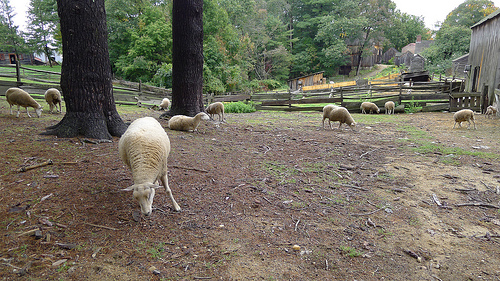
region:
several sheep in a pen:
[5, 80, 497, 241]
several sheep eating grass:
[6, 75, 493, 218]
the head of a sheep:
[116, 176, 161, 221]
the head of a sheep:
[345, 118, 360, 130]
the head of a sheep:
[193, 109, 210, 124]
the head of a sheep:
[33, 100, 43, 119]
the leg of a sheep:
[158, 172, 185, 219]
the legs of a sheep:
[313, 115, 345, 137]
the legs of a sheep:
[2, 101, 32, 121]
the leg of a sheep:
[449, 121, 476, 128]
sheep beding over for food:
[113, 113, 181, 216]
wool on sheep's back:
[134, 117, 156, 167]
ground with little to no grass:
[198, 140, 489, 274]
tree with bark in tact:
[52, 0, 124, 123]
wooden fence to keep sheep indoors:
[202, 85, 472, 113]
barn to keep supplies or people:
[463, 31, 498, 108]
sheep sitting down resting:
[166, 110, 209, 132]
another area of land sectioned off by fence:
[2, 0, 59, 70]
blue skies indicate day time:
[403, 0, 448, 12]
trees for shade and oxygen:
[203, 3, 345, 65]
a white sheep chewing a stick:
[98, 111, 186, 218]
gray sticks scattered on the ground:
[330, 162, 380, 202]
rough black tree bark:
[69, 80, 89, 105]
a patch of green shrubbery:
[220, 100, 254, 112]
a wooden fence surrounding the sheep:
[251, 90, 477, 103]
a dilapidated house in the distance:
[9, 51, 49, 62]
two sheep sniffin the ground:
[1, 82, 74, 118]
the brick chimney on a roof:
[414, 30, 424, 42]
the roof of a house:
[400, 40, 442, 54]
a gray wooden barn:
[468, 22, 498, 97]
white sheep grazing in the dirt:
[112, 114, 187, 219]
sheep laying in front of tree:
[162, 110, 207, 132]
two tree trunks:
[45, 4, 210, 129]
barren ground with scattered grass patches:
[8, 102, 491, 279]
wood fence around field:
[8, 60, 473, 116]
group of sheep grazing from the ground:
[8, 76, 496, 228]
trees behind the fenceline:
[2, 3, 470, 83]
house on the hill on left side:
[4, 15, 51, 62]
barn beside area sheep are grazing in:
[455, 15, 499, 111]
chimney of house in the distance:
[414, 26, 426, 43]